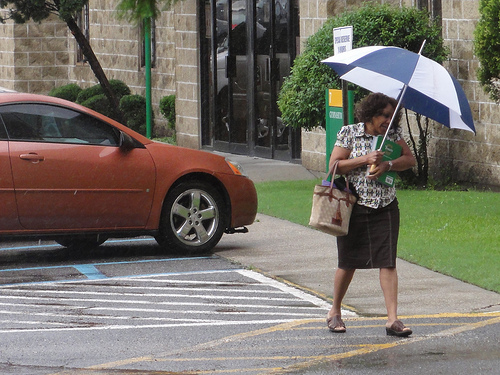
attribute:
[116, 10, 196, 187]
green pole — thin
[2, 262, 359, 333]
lines — white 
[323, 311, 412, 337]
shoes — brown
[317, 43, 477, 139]
umbrella — open, blue, white, striped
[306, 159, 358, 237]
purse — brown 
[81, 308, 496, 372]
lines — yellow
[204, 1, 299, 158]
black door — large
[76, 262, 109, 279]
line — blue 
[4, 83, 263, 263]
compact car — orange compact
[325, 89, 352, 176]
sign — green, yellow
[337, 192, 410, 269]
skirt — brown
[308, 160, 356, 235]
handbag — brown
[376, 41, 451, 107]
stripes — blue , white 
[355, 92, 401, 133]
hair — curly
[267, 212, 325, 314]
sidewalk — light, brown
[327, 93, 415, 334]
woman — brunette, caucasian, busy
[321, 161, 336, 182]
straps — brown 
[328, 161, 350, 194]
straps — brown 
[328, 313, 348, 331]
shoe — brown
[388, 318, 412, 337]
shoe — brown